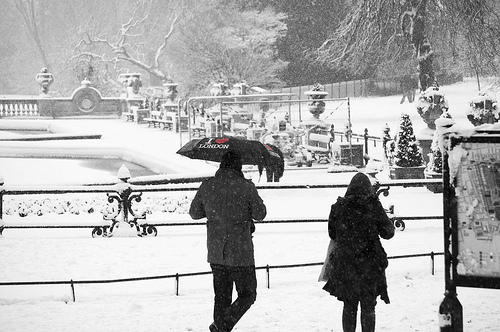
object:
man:
[188, 150, 269, 332]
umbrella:
[175, 134, 284, 178]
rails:
[0, 280, 20, 286]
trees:
[5, 0, 51, 69]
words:
[198, 144, 204, 149]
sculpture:
[35, 66, 500, 194]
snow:
[0, 0, 500, 332]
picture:
[0, 0, 500, 332]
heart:
[215, 138, 229, 144]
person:
[320, 171, 397, 332]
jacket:
[320, 194, 396, 305]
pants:
[340, 294, 378, 331]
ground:
[0, 104, 500, 332]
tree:
[303, 0, 500, 91]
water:
[0, 157, 160, 186]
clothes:
[221, 189, 224, 191]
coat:
[188, 168, 268, 267]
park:
[0, 61, 500, 332]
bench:
[143, 111, 177, 131]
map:
[443, 136, 500, 288]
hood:
[344, 171, 374, 194]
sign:
[433, 116, 499, 332]